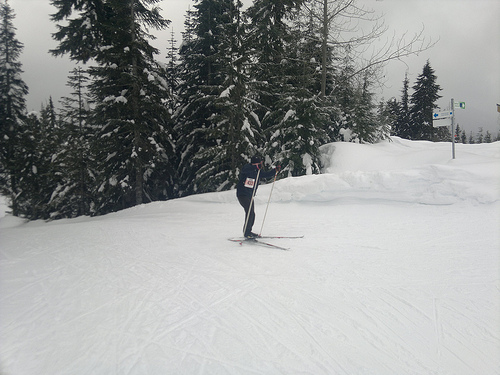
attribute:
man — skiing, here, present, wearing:
[202, 139, 295, 249]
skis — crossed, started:
[213, 208, 359, 306]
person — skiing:
[235, 156, 261, 197]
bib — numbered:
[233, 172, 262, 195]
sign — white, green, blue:
[429, 88, 450, 122]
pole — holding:
[437, 90, 467, 154]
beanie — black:
[240, 131, 270, 168]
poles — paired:
[248, 181, 287, 232]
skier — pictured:
[241, 143, 298, 206]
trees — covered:
[105, 15, 326, 136]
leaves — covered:
[76, 65, 130, 148]